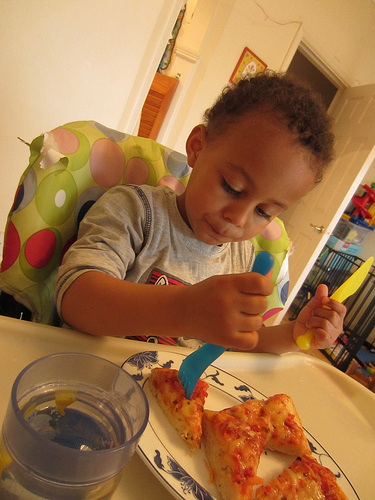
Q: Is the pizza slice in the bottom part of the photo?
A: Yes, the pizza slice is in the bottom of the image.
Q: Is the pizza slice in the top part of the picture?
A: No, the pizza slice is in the bottom of the image.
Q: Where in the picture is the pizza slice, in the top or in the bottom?
A: The pizza slice is in the bottom of the image.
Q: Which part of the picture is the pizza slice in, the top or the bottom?
A: The pizza slice is in the bottom of the image.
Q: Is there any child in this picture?
A: Yes, there is a child.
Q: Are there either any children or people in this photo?
A: Yes, there is a child.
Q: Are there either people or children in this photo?
A: Yes, there is a child.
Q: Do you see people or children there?
A: Yes, there is a child.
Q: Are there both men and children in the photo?
A: No, there is a child but no men.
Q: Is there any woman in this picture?
A: No, there are no women.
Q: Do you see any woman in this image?
A: No, there are no women.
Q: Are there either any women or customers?
A: No, there are no women or customers.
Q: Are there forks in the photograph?
A: Yes, there is a fork.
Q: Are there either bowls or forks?
A: Yes, there is a fork.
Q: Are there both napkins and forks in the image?
A: No, there is a fork but no napkins.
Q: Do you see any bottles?
A: No, there are no bottles.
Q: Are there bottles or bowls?
A: No, there are no bottles or bowls.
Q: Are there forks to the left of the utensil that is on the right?
A: Yes, there is a fork to the left of the knife.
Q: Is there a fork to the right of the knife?
A: No, the fork is to the left of the knife.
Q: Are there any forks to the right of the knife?
A: No, the fork is to the left of the knife.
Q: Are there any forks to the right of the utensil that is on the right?
A: No, the fork is to the left of the knife.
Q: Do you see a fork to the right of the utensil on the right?
A: No, the fork is to the left of the knife.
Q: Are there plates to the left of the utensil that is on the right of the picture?
A: No, there is a fork to the left of the knife.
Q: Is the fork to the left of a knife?
A: Yes, the fork is to the left of a knife.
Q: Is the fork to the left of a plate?
A: No, the fork is to the left of a knife.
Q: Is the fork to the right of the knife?
A: No, the fork is to the left of the knife.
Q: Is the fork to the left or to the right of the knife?
A: The fork is to the left of the knife.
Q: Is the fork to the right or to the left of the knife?
A: The fork is to the left of the knife.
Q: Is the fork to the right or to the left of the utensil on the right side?
A: The fork is to the left of the knife.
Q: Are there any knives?
A: Yes, there is a knife.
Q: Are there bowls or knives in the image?
A: Yes, there is a knife.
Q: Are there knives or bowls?
A: Yes, there is a knife.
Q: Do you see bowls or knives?
A: Yes, there is a knife.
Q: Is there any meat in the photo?
A: No, there is no meat.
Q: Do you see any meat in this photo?
A: No, there is no meat.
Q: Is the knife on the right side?
A: Yes, the knife is on the right of the image.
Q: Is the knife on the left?
A: No, the knife is on the right of the image.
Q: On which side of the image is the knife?
A: The knife is on the right of the image.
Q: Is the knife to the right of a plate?
A: No, the knife is to the right of the fork.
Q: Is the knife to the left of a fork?
A: No, the knife is to the right of a fork.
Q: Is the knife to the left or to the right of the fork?
A: The knife is to the right of the fork.